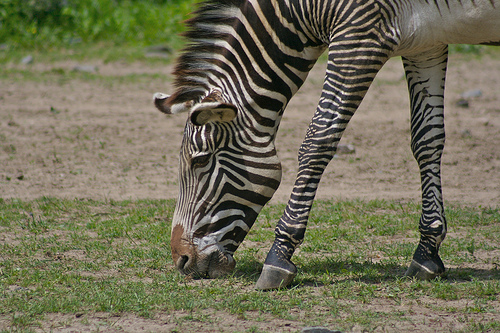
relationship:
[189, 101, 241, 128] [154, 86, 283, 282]
ear on a head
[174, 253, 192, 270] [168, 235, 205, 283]
nostril on a snout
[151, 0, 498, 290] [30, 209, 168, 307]
zebra eating grass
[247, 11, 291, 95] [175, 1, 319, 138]
pattern around a neck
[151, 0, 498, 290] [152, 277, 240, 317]
zebra eats little grass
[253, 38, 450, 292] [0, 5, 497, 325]
legs on ground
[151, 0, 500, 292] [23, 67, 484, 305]
zebra sniffs ground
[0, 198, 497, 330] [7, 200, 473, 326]
grass on section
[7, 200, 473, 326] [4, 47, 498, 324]
section of field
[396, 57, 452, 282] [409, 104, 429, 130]
leg has stripes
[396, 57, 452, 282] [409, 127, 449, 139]
leg has stripes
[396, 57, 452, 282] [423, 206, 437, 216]
leg has stripes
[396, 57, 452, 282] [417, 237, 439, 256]
leg has stripes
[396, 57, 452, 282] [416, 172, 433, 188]
leg has stripes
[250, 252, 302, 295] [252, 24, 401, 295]
hoof attached to leg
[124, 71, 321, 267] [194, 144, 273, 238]
head has stripes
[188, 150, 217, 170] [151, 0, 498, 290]
eye belongs to zebra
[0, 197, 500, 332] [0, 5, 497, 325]
grass on ground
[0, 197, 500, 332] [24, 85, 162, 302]
grass on ground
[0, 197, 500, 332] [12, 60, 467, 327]
grass on ground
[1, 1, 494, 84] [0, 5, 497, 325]
grass on ground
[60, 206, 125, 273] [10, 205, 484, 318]
green grass on ground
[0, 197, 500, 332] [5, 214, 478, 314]
grass on ground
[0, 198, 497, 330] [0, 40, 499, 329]
grass on ground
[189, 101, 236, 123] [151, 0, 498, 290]
ear of zebra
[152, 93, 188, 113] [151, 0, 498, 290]
ear of zebra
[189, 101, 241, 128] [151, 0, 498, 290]
ear of zebra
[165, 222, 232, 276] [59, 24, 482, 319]
nose of zebra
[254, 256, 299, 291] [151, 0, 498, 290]
hoof of zebra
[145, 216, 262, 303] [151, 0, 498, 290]
snout of zebra